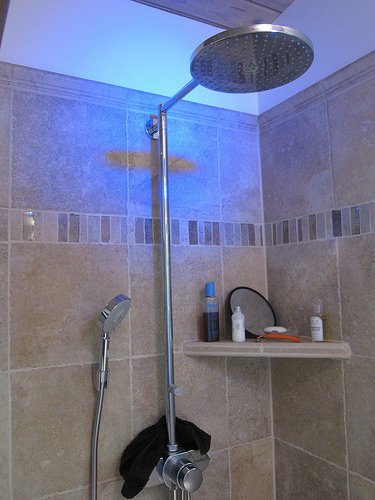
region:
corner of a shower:
[2, 6, 359, 498]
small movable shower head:
[86, 286, 143, 498]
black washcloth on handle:
[113, 403, 220, 497]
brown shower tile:
[7, 190, 87, 489]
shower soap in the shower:
[197, 268, 228, 351]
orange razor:
[255, 327, 309, 353]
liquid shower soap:
[304, 296, 353, 365]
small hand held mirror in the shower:
[225, 278, 293, 342]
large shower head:
[147, 11, 330, 156]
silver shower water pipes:
[141, 72, 212, 465]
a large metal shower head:
[176, 25, 323, 95]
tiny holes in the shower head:
[236, 40, 258, 56]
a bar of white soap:
[262, 323, 286, 331]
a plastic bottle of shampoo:
[200, 276, 220, 340]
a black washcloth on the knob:
[136, 424, 185, 465]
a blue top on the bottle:
[195, 276, 227, 300]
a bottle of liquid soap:
[301, 297, 332, 343]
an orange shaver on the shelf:
[255, 326, 302, 340]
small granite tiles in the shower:
[49, 205, 119, 246]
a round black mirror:
[238, 286, 276, 314]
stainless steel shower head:
[81, 282, 136, 359]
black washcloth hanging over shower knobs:
[111, 411, 221, 498]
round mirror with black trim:
[224, 280, 280, 353]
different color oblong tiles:
[267, 213, 350, 245]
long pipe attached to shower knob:
[154, 100, 205, 492]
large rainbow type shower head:
[180, 21, 316, 97]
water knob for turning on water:
[156, 443, 216, 497]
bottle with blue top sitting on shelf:
[199, 271, 224, 361]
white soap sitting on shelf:
[249, 316, 299, 359]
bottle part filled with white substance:
[228, 301, 248, 349]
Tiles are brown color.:
[4, 266, 95, 376]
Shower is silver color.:
[203, 20, 293, 95]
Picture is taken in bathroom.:
[35, 47, 346, 475]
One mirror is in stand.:
[225, 285, 277, 333]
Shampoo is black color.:
[199, 281, 224, 341]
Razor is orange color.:
[250, 326, 302, 343]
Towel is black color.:
[120, 405, 211, 489]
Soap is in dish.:
[262, 320, 299, 335]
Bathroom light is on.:
[97, 16, 270, 161]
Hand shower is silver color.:
[93, 289, 128, 411]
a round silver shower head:
[189, 24, 317, 106]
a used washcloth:
[116, 394, 222, 498]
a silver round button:
[157, 447, 226, 497]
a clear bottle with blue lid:
[199, 275, 223, 339]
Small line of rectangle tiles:
[15, 201, 338, 248]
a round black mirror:
[216, 278, 285, 336]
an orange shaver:
[252, 328, 300, 344]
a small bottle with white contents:
[227, 302, 250, 342]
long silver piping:
[133, 68, 212, 386]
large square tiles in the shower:
[8, 238, 355, 467]